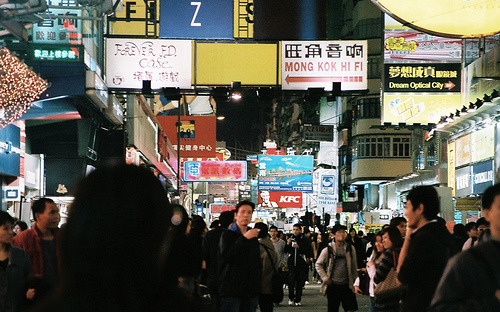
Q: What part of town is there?
A: Downtown.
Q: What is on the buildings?
A: Signs.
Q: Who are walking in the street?
A: People.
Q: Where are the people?
A: City.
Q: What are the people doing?
A: Walking.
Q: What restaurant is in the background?
A: KFC.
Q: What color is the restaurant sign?
A: Red.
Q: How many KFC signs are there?
A: One.